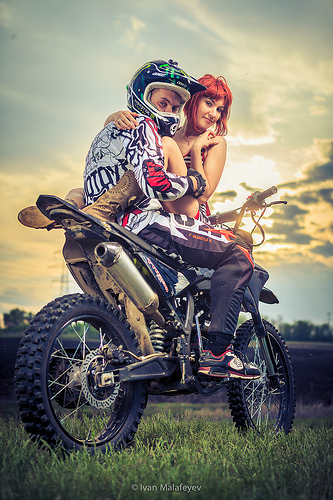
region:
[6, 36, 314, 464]
Couple sitting on a motorcycle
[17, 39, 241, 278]
Woman sits on lap on man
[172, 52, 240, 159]
Girl has red hair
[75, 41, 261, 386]
Man wears a helmet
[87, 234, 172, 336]
Motorcycle exhaust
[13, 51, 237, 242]
Woman wears brown boots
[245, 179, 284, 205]
Handle of motorcycle is black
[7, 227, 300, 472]
Motorcycle is black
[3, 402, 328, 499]
Green grass on soil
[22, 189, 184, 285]
Sit of motorcycle is black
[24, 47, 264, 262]
man and woman intertwined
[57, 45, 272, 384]
man and woman on a motorcycle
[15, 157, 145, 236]
boot with straps and circle design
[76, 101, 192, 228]
shirt with busy black and red print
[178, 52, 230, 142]
woman with chin length red hair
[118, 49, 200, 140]
man wearing helmet with green and white curves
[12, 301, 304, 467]
motorcycle parked on grass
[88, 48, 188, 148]
woman's hand on man's shoulder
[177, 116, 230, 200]
arm bent at elbow with hand on shoulder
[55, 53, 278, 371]
woman facing wrong direction on motorcycle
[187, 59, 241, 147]
her hair is red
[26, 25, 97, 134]
the sky is blue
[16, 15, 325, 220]
the sky is cloudy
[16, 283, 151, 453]
the tire is black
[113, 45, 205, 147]
the helmet is black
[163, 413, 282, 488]
the grass is green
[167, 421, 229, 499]
the grass is long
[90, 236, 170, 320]
the metal is silver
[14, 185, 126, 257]
the woman has shoes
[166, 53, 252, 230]
the girl is white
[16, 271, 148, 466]
the tire is round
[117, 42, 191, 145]
the man is wearing a helmet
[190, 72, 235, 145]
the hair is red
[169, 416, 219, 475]
the grass is green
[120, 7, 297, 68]
the sky is cloudy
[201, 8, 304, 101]
the clouds are white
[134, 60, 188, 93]
black motorcycle helmet with green writing.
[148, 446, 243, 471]
green grass on the ground.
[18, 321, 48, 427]
black rubber tire.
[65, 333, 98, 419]
silver metal spokes.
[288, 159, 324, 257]
clouds high in the sky.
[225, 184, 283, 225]
handlebars on front of motorcycle.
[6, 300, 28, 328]
green leaves on tree.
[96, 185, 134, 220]
brown cowboy boots on woman.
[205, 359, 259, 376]
black, red, and white tennis shoes.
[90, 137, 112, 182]
white jacket with black writing.